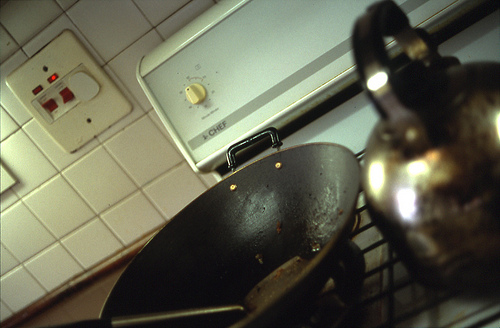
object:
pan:
[99, 127, 362, 328]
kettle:
[351, 0, 499, 293]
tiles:
[1, 0, 220, 327]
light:
[365, 70, 389, 93]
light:
[366, 156, 430, 225]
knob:
[182, 82, 206, 105]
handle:
[225, 126, 284, 168]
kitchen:
[1, 0, 499, 327]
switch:
[41, 97, 58, 114]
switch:
[59, 86, 74, 104]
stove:
[136, 0, 497, 328]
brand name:
[200, 119, 229, 141]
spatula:
[48, 255, 309, 327]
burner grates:
[345, 147, 450, 326]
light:
[49, 74, 57, 84]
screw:
[274, 163, 283, 169]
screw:
[226, 180, 237, 191]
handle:
[351, 0, 430, 119]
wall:
[1, 0, 227, 327]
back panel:
[135, 1, 499, 177]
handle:
[40, 313, 112, 327]